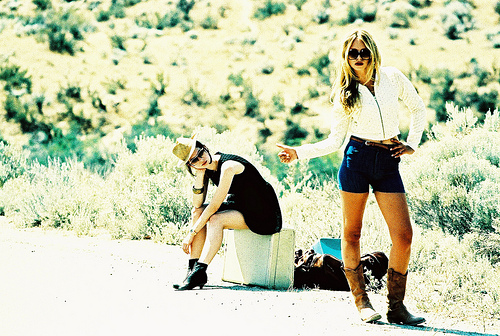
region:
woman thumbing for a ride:
[262, 29, 432, 319]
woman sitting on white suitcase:
[165, 128, 292, 295]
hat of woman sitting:
[170, 126, 195, 161]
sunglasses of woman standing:
[342, 45, 365, 59]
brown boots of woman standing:
[331, 254, 419, 325]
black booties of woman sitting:
[168, 254, 210, 289]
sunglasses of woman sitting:
[186, 149, 204, 165]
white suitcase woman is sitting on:
[209, 229, 289, 289]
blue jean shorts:
[334, 138, 411, 185]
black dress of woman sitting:
[205, 153, 282, 239]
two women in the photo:
[116, 28, 447, 273]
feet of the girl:
[155, 248, 217, 303]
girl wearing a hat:
[145, 109, 294, 254]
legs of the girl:
[323, 221, 445, 314]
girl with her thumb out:
[259, 38, 429, 247]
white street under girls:
[88, 278, 140, 326]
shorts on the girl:
[326, 122, 413, 205]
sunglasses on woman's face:
[335, 37, 383, 73]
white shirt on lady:
[346, 74, 409, 130]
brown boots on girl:
[329, 260, 434, 323]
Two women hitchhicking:
[171, 29, 424, 325]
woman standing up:
[281, 32, 424, 324]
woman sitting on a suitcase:
[172, 135, 294, 295]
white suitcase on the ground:
[223, 229, 293, 287]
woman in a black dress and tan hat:
[172, 140, 294, 288]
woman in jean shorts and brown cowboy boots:
[281, 30, 426, 326]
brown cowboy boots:
[344, 264, 422, 325]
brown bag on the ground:
[301, 250, 387, 290]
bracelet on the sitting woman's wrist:
[191, 185, 202, 193]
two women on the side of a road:
[0, 28, 430, 334]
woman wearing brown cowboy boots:
[341, 260, 426, 328]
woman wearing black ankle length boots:
[171, 255, 211, 291]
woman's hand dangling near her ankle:
[180, 159, 244, 255]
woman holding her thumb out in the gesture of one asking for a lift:
[275, 28, 386, 163]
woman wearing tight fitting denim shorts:
[340, 134, 410, 194]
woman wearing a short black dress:
[206, 149, 283, 234]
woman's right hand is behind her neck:
[182, 144, 215, 184]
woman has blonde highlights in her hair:
[334, 28, 380, 108]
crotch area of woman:
[368, 171, 380, 184]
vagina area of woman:
[364, 170, 383, 191]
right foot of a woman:
[358, 304, 378, 324]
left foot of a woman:
[393, 225, 417, 242]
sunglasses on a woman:
[348, 47, 370, 61]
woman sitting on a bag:
[164, 131, 292, 288]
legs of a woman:
[339, 186, 439, 326]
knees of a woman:
[338, 220, 418, 247]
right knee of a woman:
[341, 223, 366, 250]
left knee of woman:
[393, 227, 415, 247]